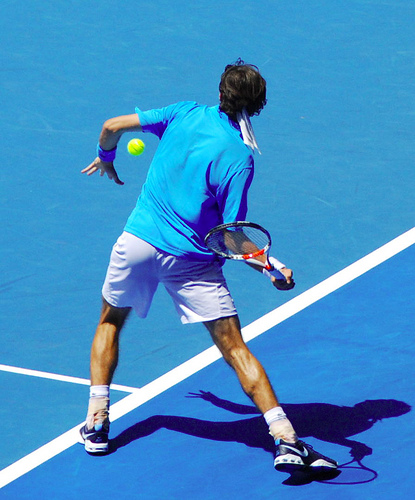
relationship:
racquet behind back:
[197, 215, 296, 293] [159, 134, 215, 241]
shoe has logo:
[239, 407, 377, 498] [279, 441, 310, 457]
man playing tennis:
[42, 26, 327, 303] [87, 91, 345, 288]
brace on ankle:
[261, 409, 300, 452] [256, 409, 299, 434]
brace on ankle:
[82, 384, 111, 430] [80, 388, 116, 409]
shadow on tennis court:
[105, 388, 415, 485] [0, 0, 413, 498]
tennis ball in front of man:
[125, 138, 144, 155] [75, 57, 340, 477]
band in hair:
[234, 108, 263, 148] [218, 64, 270, 114]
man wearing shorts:
[75, 57, 340, 477] [101, 225, 239, 325]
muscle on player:
[235, 360, 271, 396] [98, 59, 335, 415]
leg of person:
[75, 230, 158, 453] [80, 56, 338, 472]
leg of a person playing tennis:
[225, 384, 305, 500] [108, 236, 332, 368]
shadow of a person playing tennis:
[120, 386, 399, 500] [129, 381, 399, 469]